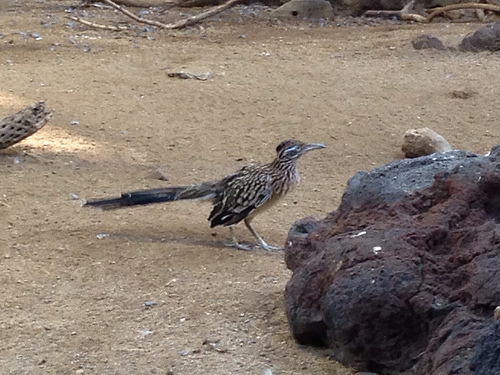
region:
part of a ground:
[88, 225, 123, 262]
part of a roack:
[347, 254, 378, 300]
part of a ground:
[179, 287, 207, 321]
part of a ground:
[150, 303, 187, 339]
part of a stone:
[361, 284, 397, 341]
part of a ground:
[182, 298, 212, 338]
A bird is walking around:
[1, 15, 486, 360]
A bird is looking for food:
[31, 47, 474, 357]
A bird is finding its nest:
[13, 51, 473, 357]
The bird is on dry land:
[10, 25, 485, 337]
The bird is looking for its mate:
[52, 32, 462, 342]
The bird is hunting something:
[17, 17, 453, 368]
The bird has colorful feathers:
[21, 5, 488, 346]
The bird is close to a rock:
[35, 45, 480, 355]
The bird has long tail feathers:
[50, 35, 465, 350]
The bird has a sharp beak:
[31, 25, 461, 359]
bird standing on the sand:
[83, 138, 325, 254]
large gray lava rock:
[284, 155, 498, 369]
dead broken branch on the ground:
[104, 0, 245, 30]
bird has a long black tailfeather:
[83, 138, 325, 253]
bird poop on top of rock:
[345, 225, 384, 260]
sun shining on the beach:
[1, 93, 108, 156]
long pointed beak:
[301, 138, 328, 154]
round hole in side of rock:
[288, 6, 298, 18]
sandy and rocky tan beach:
[5, 5, 490, 369]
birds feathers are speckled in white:
[83, 138, 328, 253]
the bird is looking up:
[229, 113, 336, 240]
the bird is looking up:
[233, 120, 330, 188]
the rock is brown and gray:
[293, 205, 378, 314]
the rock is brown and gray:
[271, 185, 409, 359]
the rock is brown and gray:
[341, 82, 458, 288]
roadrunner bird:
[77, 135, 330, 255]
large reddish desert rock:
[277, 147, 495, 373]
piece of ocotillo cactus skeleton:
[1, 96, 51, 153]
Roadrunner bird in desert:
[3, 0, 496, 363]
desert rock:
[395, 125, 457, 159]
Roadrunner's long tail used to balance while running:
[80, 173, 218, 213]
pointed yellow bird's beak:
[303, 140, 325, 151]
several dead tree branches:
[5, 0, 495, 30]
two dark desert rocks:
[405, 20, 495, 55]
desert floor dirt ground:
[2, 30, 495, 370]